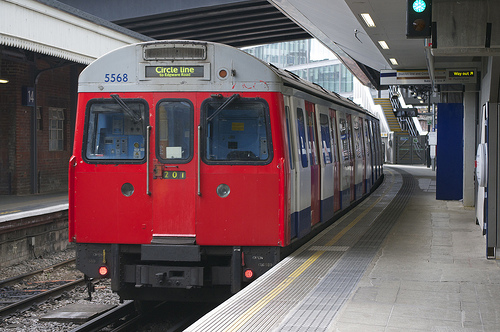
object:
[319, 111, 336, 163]
window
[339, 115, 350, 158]
window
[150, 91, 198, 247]
door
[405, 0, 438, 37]
traffic signal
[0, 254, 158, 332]
railway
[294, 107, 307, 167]
side windows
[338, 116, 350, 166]
window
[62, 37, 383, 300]
train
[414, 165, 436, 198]
ground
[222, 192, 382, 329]
yellow line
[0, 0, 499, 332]
train terminal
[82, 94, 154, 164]
window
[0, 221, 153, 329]
line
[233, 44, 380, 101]
background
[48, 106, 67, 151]
window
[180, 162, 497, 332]
walkway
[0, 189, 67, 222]
walkway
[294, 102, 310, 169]
window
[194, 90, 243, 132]
wiper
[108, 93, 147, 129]
wiper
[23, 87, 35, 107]
number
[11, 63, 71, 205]
wall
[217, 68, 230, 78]
lights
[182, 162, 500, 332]
grey stone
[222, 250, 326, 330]
lines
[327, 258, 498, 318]
ground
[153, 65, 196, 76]
words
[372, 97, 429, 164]
stairs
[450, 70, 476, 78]
sign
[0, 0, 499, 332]
station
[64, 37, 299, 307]
front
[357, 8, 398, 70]
lights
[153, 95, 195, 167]
window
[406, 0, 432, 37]
light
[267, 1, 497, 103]
roof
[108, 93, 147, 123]
wiper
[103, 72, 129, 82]
blue numbers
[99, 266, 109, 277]
light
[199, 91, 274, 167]
window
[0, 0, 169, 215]
building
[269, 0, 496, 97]
ceiling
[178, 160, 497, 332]
train platform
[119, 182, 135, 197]
headlights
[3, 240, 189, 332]
gravel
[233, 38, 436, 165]
buildings